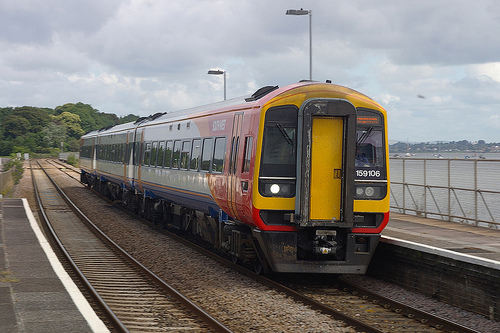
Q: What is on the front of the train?
A: A door.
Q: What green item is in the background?
A: Trees.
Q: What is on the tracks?
A: A train.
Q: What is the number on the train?
A: 159106.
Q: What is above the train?
A: Cloudy sky.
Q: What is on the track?
A: Yellow train.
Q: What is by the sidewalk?
A: Two train tracks.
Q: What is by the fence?
A: Water.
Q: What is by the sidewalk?
A: Metal poles.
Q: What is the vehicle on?
A: Train tracks.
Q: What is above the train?
A: Two lights.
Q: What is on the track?
A: Yellow door on train.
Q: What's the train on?
A: The track.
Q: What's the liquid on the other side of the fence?
A: Water.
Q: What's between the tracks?
A: Rocks.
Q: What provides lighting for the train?
A: Light posts.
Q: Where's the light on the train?
A: The front.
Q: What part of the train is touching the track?
A: The bottom.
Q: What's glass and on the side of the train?
A: Windows.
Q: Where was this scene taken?
A: Oceanside.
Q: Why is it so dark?
A: It is going to rain.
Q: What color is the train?
A: Yellow, red and grey.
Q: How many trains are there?
A: One.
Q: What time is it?
A: 10:00 a.m.